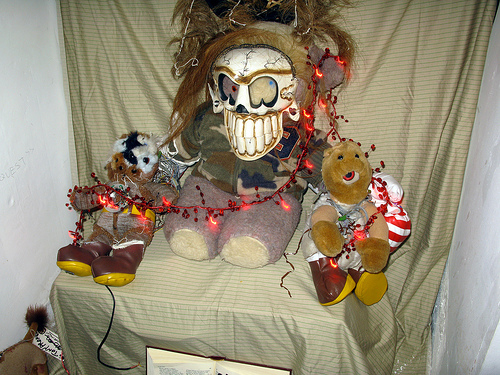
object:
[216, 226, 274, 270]
feet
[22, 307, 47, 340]
tail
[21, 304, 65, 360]
plush toy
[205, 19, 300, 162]
skull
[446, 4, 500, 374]
wall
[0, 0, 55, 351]
wall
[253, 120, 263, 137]
teeth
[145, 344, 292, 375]
book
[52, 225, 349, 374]
table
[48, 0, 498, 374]
sheet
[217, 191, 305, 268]
leg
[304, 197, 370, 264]
sweater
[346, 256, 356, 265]
part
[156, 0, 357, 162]
mask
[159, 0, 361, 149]
hair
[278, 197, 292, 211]
lights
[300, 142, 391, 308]
bear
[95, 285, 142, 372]
wiring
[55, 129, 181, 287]
bears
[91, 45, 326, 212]
wiring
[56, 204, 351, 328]
board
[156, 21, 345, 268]
teddy bear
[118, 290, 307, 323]
edge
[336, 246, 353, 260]
edge